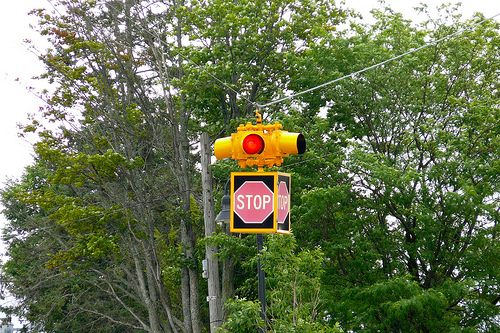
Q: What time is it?
A: Afternoon.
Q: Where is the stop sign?
A: Below the light.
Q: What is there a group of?
A: Tree trunks.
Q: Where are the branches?
A: On the tree.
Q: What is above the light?
A: A rope.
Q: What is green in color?
A: The trees.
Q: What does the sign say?
A: Stop.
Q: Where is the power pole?
A: In the trees.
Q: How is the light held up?
A: Pole.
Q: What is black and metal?
A: Post.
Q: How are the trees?
A: In a group.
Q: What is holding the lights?
A: Wires.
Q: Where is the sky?
A: Behind the trees.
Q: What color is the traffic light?
A: Red.